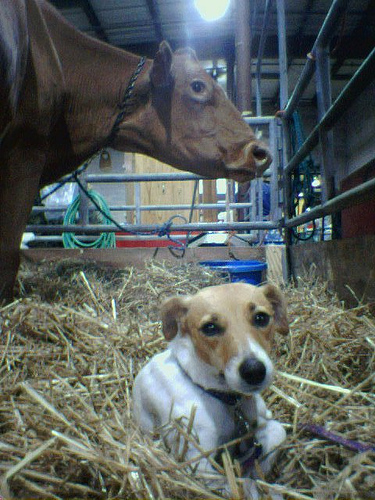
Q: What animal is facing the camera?
A: The dog.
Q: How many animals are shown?
A: Two.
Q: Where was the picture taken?
A: A barn.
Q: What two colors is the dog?
A: Brown and white.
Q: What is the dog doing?
A: Laying down.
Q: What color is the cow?
A: Brown.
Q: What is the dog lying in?
A: Straw.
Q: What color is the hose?
A: Green.